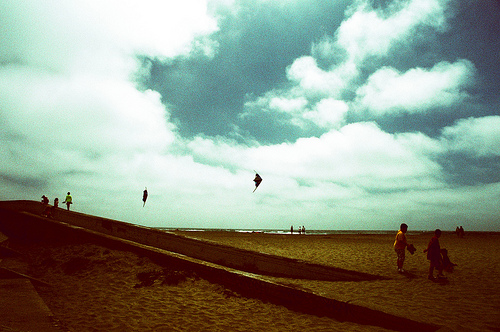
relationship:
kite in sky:
[251, 169, 263, 190] [1, 0, 498, 229]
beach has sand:
[126, 230, 498, 328] [0, 199, 498, 330]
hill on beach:
[1, 199, 451, 330] [126, 230, 498, 328]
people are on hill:
[41, 190, 71, 216] [1, 199, 451, 330]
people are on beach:
[289, 222, 463, 282] [126, 230, 498, 328]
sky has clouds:
[1, 0, 498, 229] [0, 2, 499, 231]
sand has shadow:
[0, 199, 498, 330] [400, 267, 452, 282]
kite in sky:
[139, 189, 149, 203] [1, 0, 498, 229]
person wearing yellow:
[394, 225, 416, 271] [393, 230, 408, 247]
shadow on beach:
[400, 267, 452, 282] [126, 230, 498, 328]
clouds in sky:
[0, 2, 499, 231] [1, 0, 498, 229]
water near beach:
[148, 227, 422, 234] [126, 230, 498, 328]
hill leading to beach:
[1, 199, 451, 330] [126, 230, 498, 328]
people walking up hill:
[41, 190, 71, 216] [1, 199, 451, 330]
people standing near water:
[290, 226, 309, 233] [148, 227, 422, 234]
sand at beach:
[0, 199, 498, 330] [126, 230, 498, 328]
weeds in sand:
[137, 262, 193, 288] [0, 199, 498, 330]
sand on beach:
[0, 199, 498, 330] [126, 230, 498, 328]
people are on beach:
[290, 226, 309, 233] [126, 230, 498, 328]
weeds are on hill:
[137, 262, 193, 288] [1, 199, 451, 330]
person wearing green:
[60, 190, 71, 211] [64, 196, 71, 203]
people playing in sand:
[289, 222, 463, 282] [0, 199, 498, 330]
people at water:
[290, 226, 309, 233] [148, 227, 422, 234]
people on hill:
[41, 190, 71, 216] [1, 199, 451, 330]